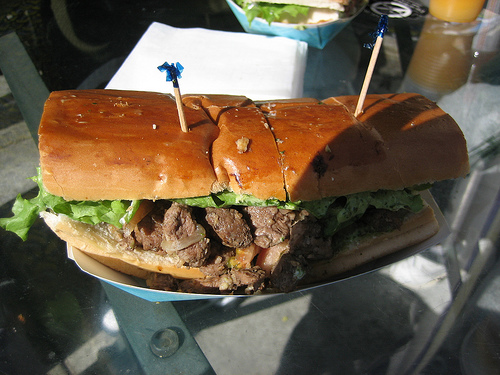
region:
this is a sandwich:
[28, 70, 468, 300]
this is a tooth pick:
[151, 48, 208, 136]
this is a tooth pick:
[343, 0, 425, 127]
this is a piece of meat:
[205, 198, 255, 256]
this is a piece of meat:
[158, 202, 222, 274]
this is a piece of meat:
[291, 213, 326, 273]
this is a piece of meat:
[126, 211, 171, 263]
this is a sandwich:
[19, 76, 465, 310]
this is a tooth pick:
[145, 43, 205, 130]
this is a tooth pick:
[334, 12, 406, 124]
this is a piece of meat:
[160, 195, 231, 279]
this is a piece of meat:
[203, 196, 259, 243]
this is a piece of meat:
[245, 208, 299, 255]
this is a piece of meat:
[220, 251, 265, 293]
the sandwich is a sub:
[60, 64, 478, 291]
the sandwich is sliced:
[65, 103, 289, 177]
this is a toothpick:
[117, 60, 231, 141]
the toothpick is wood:
[117, 54, 238, 122]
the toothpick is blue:
[158, 55, 215, 106]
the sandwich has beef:
[30, 141, 344, 252]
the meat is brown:
[185, 224, 317, 274]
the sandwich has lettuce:
[40, 161, 174, 242]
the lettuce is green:
[52, 187, 154, 238]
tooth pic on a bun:
[155, 60, 202, 140]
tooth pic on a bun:
[350, 7, 390, 142]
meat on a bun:
[160, 205, 217, 267]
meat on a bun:
[211, 205, 254, 245]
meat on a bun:
[257, 202, 287, 247]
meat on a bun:
[300, 227, 342, 254]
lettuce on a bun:
[370, 187, 410, 217]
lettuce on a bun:
[17, 200, 97, 216]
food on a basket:
[10, 65, 457, 310]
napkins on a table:
[204, 45, 278, 86]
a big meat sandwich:
[38, 92, 465, 300]